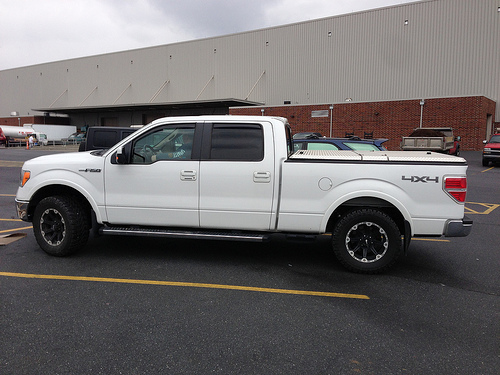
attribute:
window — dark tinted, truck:
[204, 117, 278, 171]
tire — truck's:
[27, 193, 89, 260]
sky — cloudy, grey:
[1, 2, 390, 76]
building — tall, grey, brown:
[2, 0, 498, 162]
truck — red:
[398, 120, 463, 159]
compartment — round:
[313, 175, 336, 194]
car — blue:
[293, 131, 388, 152]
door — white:
[103, 118, 203, 232]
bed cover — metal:
[287, 145, 466, 165]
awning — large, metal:
[20, 97, 297, 139]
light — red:
[442, 175, 466, 205]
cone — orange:
[23, 142, 28, 159]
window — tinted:
[210, 115, 278, 165]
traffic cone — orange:
[23, 140, 30, 150]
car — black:
[76, 124, 186, 156]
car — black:
[291, 132, 320, 139]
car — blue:
[297, 133, 394, 153]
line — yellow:
[29, 267, 382, 314]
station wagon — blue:
[294, 137, 386, 151]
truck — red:
[22, 120, 455, 262]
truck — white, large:
[12, 107, 470, 274]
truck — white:
[39, 61, 464, 283]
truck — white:
[34, 76, 484, 310]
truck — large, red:
[481, 130, 499, 167]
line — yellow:
[1, 270, 368, 300]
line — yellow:
[1, 217, 24, 222]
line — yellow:
[0, 192, 17, 197]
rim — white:
[341, 219, 393, 263]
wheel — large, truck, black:
[338, 201, 407, 271]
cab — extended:
[204, 113, 289, 232]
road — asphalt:
[10, 240, 467, 373]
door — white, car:
[102, 124, 199, 216]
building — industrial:
[4, 7, 484, 154]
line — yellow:
[6, 254, 383, 311]